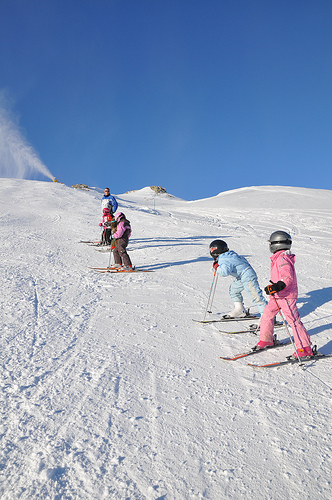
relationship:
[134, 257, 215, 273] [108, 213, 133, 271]
shadow cast by child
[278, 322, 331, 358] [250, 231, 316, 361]
shadow cast by child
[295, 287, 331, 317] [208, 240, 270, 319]
shadow cast by child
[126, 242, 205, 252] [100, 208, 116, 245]
shadow cast by child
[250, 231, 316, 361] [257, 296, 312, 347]
child wearing snow pants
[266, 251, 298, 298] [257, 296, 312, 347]
jacket above snow pants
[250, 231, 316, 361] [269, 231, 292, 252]
child wearing helmet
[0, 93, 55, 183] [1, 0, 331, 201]
snow blowing against sky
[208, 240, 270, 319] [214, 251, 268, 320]
child wearing snowsuit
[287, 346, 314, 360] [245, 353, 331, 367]
boot on top of ski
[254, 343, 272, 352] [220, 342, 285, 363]
boot on top of ski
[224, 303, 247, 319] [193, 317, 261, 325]
boot on top of ski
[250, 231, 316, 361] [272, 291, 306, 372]
child holding ski pole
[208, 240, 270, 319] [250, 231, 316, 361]
child next to child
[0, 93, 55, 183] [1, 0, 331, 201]
snow blowing in sky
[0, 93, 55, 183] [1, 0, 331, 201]
snow up in sky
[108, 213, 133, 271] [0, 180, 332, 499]
child standing on snow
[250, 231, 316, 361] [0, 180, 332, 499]
child standing on snow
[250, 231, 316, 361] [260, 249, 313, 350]
child wearing snowsuit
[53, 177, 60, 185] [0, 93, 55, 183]
machine blowing snow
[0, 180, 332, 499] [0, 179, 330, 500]
snow on top of mountain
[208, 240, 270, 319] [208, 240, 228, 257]
child wearing helmet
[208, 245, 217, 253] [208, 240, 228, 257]
logo attached to helmet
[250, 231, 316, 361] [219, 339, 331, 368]
child standing on skis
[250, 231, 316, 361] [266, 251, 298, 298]
child wearing jacket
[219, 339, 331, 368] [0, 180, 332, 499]
skis on top of snow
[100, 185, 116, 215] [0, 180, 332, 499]
skier standing on snow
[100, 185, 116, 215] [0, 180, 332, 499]
skier standing in snow